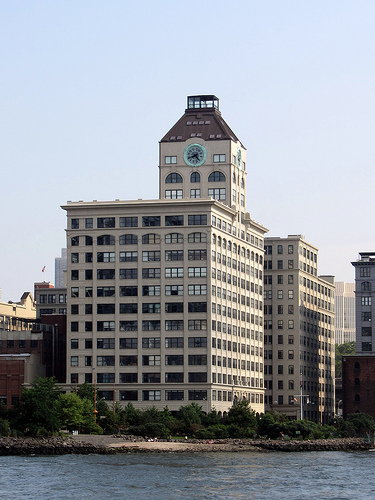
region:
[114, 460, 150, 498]
The water in the forefront is dark.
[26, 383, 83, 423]
The trees in the forefront are green.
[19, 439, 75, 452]
The coastline has rocks.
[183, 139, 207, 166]
The clock is green and black.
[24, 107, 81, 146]
The sky is clear.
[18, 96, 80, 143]
The sky is blue.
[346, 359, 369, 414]
The building on the right is brown.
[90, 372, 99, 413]
The pole is tall.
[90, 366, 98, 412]
The pole is brown.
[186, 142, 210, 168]
The clock numbers are black.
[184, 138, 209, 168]
clock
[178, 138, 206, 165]
clock in tower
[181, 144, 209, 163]
black gray and green clock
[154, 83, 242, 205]
clock tower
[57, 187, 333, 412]
large tan building by water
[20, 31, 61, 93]
white clouds in blue sky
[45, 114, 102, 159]
white clouds in blue sky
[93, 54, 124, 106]
white clouds in blue sky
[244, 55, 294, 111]
white clouds in blue sky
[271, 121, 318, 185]
white clouds in blue sky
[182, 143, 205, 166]
a green circular clock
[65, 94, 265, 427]
a tall building with many windows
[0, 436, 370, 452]
a rocky coastline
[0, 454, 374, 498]
still blue clear water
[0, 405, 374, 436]
a row of trees along the coast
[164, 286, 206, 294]
a row of windows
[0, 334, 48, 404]
a red brick building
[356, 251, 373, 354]
a building with tall circular windows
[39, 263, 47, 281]
a flag in the distance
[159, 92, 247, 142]
the roof to a building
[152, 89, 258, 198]
Clock is located high up on the building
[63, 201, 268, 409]
Building with lots of windows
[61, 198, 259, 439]
Building behind bushes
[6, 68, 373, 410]
There are several buildings located next to each other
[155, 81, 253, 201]
There are three windows that are half-circles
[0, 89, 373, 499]
The buildings are right on the edge of a lake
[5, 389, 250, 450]
There's a walkway from the buildings to the lake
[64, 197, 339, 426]
These buildings looks identical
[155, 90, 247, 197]
The clock is green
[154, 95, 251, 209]
Theres a rooftop on this building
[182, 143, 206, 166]
a circular green clock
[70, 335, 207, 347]
a row of windows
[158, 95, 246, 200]
a tall tower attached to a building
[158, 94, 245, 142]
the roof of a building